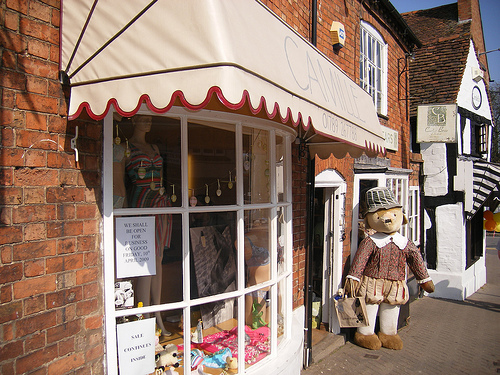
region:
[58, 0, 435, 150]
white awning with red scalloped trim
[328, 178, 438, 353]
large teddy bear wearing hat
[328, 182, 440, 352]
large brown teddy bear carrying bag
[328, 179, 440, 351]
large teddy bear wearing dress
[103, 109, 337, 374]
white wooden framed bay window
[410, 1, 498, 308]
white house with red roof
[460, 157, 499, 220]
black and white awning hanging from white house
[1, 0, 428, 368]
red brick building with white window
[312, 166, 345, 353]
white doorway in red building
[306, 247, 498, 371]
grey tiled brick sidewalk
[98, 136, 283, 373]
Window on a store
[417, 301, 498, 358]
Gray brick sidewalk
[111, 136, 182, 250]
Dress in a window.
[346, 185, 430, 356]
Tall bear outside a store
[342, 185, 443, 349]
Bear standing on a sidewalk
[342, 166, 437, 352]
Tall bear on a sidewalk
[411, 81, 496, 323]
White building on a street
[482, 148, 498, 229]
Black and white awning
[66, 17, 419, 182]
Tan and red awning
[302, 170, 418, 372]
Door to a store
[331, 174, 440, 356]
brown teddy bear standing on sidewalk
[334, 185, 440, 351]
brown teddy bear carrying bag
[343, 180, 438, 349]
brown teddy bear wearing dress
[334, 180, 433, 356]
brown teddy bear wearing hat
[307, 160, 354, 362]
white doorway in brick building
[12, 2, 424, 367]
red brick building on sidewalk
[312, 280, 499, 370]
gray brick tiled sidewalk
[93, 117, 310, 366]
wooden white framed bay window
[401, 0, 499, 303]
white building with tiled roof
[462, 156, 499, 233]
white and black awning in front of white building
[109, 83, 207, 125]
red scalloped edge of overhang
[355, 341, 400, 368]
small brown spot on ground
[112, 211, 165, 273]
large square sign in store window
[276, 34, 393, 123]
large gray sign on building front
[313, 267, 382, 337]
brown bag in bear's hand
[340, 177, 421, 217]
large black hat with white stripes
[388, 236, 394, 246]
large button on shirt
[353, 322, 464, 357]
large brown cuddly shoes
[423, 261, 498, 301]
white bottom of building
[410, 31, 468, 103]
red and black tiles on roof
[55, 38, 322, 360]
charming shop window filled with merchandise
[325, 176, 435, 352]
large teddy bear in historic outfit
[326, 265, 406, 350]
bear carrying shopping bag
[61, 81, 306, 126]
scalloped edge of awning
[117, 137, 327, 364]
panes over curved window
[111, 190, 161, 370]
signs hung on side of window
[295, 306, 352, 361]
step at entrance to shop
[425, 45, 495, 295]
building with black and white facade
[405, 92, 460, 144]
square sign hung above shop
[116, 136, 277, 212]
pendents hanging across the window